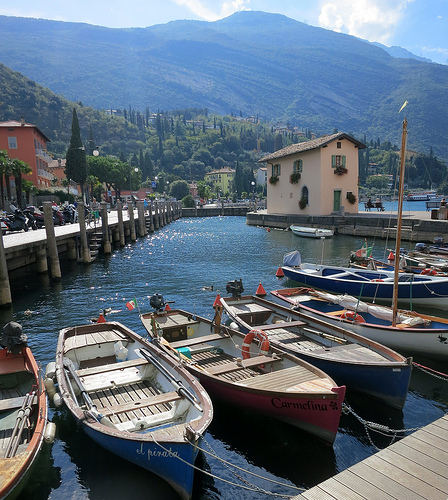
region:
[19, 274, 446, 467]
a fleet of boats at the dock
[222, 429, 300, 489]
the water is wavy and blue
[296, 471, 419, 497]
the dock is made of wood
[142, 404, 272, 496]
ropes secure the boat to the dock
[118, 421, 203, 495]
white writing is on the boat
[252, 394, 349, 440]
black writing is on the boat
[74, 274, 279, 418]
flags hang from the boat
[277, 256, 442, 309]
the boat is blue and white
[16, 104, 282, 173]
trees are in the distance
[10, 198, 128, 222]
motorcycles are parked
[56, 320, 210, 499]
blue boat floating in the water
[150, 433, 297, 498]
rope tied to boat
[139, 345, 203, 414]
oars inside boat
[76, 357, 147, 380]
wooden bench inside a boat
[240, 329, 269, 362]
orange life preserver inside boat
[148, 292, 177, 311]
outboard motor attached to boat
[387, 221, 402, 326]
tall mast attached to boat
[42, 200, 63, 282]
wooden pilings in the water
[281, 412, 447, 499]
wooden dock in front of boat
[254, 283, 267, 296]
orange buoy bobbing in the water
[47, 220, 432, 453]
body of water with boats in it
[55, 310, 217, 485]
blue boat in water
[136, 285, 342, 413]
pinkish boat in water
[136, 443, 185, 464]
lettering on blue boat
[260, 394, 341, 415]
lettering on pink boat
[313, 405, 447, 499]
deck near the water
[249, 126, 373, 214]
building on island in water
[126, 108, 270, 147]
trees in the distance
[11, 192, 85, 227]
group of motorized bikes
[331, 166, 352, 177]
plant in window on building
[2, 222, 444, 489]
several boats are docked here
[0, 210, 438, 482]
the boats are on the water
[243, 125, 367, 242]
a building is at the end of this port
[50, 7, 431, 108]
a mountain is in the background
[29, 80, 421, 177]
several trees are growing on the hillside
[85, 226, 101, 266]
some stairs leading to and from the water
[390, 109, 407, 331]
the boat has a pole in the middle of it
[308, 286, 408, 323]
the sail is put away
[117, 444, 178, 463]
the name of this boat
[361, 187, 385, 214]
people are sitting on the bench in the background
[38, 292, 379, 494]
Boats tied up at dock.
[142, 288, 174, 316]
Motor on back of boat.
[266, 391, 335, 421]
Name of boat written in black.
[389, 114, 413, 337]
Tall mast on sailboat.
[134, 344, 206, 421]
Oars mounted on side of boat.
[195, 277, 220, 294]
Duck floating in water.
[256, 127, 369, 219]
House standing on end of pier.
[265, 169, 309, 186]
Window planters on side of house.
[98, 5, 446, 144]
Mountain rising in distance behind town.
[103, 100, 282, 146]
Homes on slop of mountain behind marina.